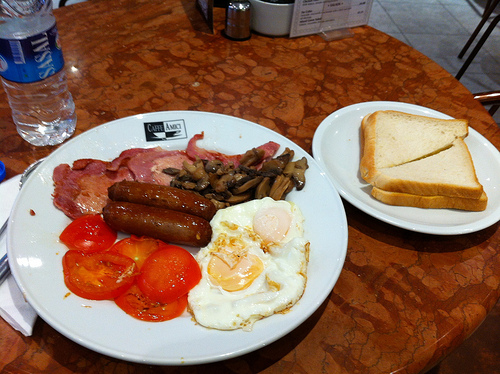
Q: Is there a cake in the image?
A: No, there are no cakes.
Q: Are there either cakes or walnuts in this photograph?
A: No, there are no cakes or walnuts.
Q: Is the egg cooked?
A: Yes, the egg is cooked.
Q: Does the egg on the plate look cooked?
A: Yes, the egg is cooked.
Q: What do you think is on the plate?
A: The egg is on the plate.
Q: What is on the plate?
A: The egg is on the plate.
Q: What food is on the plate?
A: The food is an egg.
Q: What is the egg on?
A: The egg is on the plate.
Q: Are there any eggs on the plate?
A: Yes, there is an egg on the plate.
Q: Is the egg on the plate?
A: Yes, the egg is on the plate.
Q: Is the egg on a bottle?
A: No, the egg is on the plate.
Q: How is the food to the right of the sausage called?
A: The food is an egg.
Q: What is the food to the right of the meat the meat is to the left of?
A: The food is an egg.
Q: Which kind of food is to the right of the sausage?
A: The food is an egg.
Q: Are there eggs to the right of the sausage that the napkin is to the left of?
A: Yes, there is an egg to the right of the sausage.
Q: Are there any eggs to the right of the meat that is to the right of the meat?
A: Yes, there is an egg to the right of the sausage.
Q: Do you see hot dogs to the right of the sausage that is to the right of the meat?
A: No, there is an egg to the right of the sausage.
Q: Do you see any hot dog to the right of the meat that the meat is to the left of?
A: No, there is an egg to the right of the sausage.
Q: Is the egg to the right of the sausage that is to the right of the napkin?
A: Yes, the egg is to the right of the sausage.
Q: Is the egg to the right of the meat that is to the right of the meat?
A: Yes, the egg is to the right of the sausage.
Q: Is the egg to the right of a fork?
A: No, the egg is to the right of the sausage.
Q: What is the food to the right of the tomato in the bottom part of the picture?
A: The food is an egg.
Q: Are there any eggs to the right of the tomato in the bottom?
A: Yes, there is an egg to the right of the tomato.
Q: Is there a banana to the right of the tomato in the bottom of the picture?
A: No, there is an egg to the right of the tomato.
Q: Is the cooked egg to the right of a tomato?
A: Yes, the egg is to the right of a tomato.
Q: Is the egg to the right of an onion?
A: No, the egg is to the right of a tomato.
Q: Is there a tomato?
A: Yes, there is a tomato.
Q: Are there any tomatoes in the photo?
A: Yes, there is a tomato.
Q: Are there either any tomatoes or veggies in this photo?
A: Yes, there is a tomato.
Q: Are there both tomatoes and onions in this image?
A: No, there is a tomato but no onions.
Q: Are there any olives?
A: No, there are no olives.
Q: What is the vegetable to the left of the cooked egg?
A: The vegetable is a tomato.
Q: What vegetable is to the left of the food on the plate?
A: The vegetable is a tomato.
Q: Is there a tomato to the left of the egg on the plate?
A: Yes, there is a tomato to the left of the egg.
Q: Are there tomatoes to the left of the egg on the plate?
A: Yes, there is a tomato to the left of the egg.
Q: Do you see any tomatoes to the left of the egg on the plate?
A: Yes, there is a tomato to the left of the egg.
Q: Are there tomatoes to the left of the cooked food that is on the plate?
A: Yes, there is a tomato to the left of the egg.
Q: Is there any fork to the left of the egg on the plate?
A: No, there is a tomato to the left of the egg.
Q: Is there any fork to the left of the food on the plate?
A: No, there is a tomato to the left of the egg.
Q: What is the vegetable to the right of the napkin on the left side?
A: The vegetable is a tomato.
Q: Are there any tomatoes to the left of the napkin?
A: No, the tomato is to the right of the napkin.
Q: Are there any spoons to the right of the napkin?
A: No, there is a tomato to the right of the napkin.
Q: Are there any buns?
A: No, there are no buns.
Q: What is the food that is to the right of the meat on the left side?
A: The food is a sausage.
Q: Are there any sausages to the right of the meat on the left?
A: Yes, there is a sausage to the right of the meat.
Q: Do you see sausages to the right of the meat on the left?
A: Yes, there is a sausage to the right of the meat.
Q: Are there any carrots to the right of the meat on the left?
A: No, there is a sausage to the right of the meat.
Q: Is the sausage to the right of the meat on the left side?
A: Yes, the sausage is to the right of the meat.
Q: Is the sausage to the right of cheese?
A: No, the sausage is to the right of the meat.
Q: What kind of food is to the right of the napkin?
A: The food is a sausage.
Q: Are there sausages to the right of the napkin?
A: Yes, there is a sausage to the right of the napkin.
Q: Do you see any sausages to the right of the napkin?
A: Yes, there is a sausage to the right of the napkin.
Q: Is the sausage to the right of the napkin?
A: Yes, the sausage is to the right of the napkin.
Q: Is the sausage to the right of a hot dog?
A: No, the sausage is to the right of the napkin.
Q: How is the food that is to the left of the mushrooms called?
A: The food is a sausage.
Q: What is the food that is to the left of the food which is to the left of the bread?
A: The food is a sausage.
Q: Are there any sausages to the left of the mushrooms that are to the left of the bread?
A: Yes, there is a sausage to the left of the mushrooms.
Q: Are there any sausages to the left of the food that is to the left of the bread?
A: Yes, there is a sausage to the left of the mushrooms.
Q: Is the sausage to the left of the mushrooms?
A: Yes, the sausage is to the left of the mushrooms.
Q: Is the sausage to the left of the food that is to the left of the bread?
A: Yes, the sausage is to the left of the mushrooms.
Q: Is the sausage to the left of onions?
A: No, the sausage is to the left of the mushrooms.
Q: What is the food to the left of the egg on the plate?
A: The food is a sausage.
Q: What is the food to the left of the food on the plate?
A: The food is a sausage.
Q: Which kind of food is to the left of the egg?
A: The food is a sausage.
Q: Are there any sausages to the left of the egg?
A: Yes, there is a sausage to the left of the egg.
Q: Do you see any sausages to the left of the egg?
A: Yes, there is a sausage to the left of the egg.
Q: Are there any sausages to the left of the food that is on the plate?
A: Yes, there is a sausage to the left of the egg.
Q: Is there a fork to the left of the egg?
A: No, there is a sausage to the left of the egg.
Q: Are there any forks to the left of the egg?
A: No, there is a sausage to the left of the egg.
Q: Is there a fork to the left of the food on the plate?
A: No, there is a sausage to the left of the egg.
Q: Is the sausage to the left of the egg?
A: Yes, the sausage is to the left of the egg.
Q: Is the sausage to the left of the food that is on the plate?
A: Yes, the sausage is to the left of the egg.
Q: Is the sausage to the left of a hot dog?
A: No, the sausage is to the left of the egg.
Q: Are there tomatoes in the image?
A: Yes, there is a tomato.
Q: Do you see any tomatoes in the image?
A: Yes, there is a tomato.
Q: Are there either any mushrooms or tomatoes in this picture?
A: Yes, there is a tomato.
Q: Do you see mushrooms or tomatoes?
A: Yes, there is a tomato.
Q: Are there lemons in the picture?
A: No, there are no lemons.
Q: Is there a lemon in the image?
A: No, there are no lemons.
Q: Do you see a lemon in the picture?
A: No, there are no lemons.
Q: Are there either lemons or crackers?
A: No, there are no lemons or crackers.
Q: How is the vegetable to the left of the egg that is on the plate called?
A: The vegetable is a tomato.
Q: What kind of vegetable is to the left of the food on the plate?
A: The vegetable is a tomato.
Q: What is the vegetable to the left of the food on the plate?
A: The vegetable is a tomato.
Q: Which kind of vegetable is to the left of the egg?
A: The vegetable is a tomato.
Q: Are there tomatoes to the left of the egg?
A: Yes, there is a tomato to the left of the egg.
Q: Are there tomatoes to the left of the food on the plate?
A: Yes, there is a tomato to the left of the egg.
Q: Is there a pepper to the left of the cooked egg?
A: No, there is a tomato to the left of the egg.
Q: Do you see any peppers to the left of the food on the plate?
A: No, there is a tomato to the left of the egg.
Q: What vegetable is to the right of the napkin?
A: The vegetable is a tomato.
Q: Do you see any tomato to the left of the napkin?
A: No, the tomato is to the right of the napkin.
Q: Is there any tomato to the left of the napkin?
A: No, the tomato is to the right of the napkin.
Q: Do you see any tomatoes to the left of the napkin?
A: No, the tomato is to the right of the napkin.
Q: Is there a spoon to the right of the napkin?
A: No, there is a tomato to the right of the napkin.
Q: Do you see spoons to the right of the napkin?
A: No, there is a tomato to the right of the napkin.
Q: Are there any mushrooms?
A: Yes, there are mushrooms.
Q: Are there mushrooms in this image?
A: Yes, there are mushrooms.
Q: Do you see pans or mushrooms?
A: Yes, there are mushrooms.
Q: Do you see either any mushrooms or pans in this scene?
A: Yes, there are mushrooms.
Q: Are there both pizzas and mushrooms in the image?
A: No, there are mushrooms but no pizzas.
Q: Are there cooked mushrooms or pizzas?
A: Yes, there are cooked mushrooms.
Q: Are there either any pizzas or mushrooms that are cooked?
A: Yes, the mushrooms are cooked.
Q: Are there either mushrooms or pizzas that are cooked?
A: Yes, the mushrooms are cooked.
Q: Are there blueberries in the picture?
A: No, there are no blueberries.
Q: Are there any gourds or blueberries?
A: No, there are no blueberries or gourds.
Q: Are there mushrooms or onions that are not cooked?
A: No, there are mushrooms but they are cooked.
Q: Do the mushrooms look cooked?
A: Yes, the mushrooms are cooked.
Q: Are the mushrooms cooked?
A: Yes, the mushrooms are cooked.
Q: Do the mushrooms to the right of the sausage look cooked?
A: Yes, the mushrooms are cooked.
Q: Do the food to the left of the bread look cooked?
A: Yes, the mushrooms are cooked.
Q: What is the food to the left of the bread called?
A: The food is mushrooms.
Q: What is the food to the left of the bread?
A: The food is mushrooms.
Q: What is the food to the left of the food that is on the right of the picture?
A: The food is mushrooms.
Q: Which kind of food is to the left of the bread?
A: The food is mushrooms.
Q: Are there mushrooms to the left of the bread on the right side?
A: Yes, there are mushrooms to the left of the bread.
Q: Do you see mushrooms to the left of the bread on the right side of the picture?
A: Yes, there are mushrooms to the left of the bread.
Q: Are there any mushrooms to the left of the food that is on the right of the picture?
A: Yes, there are mushrooms to the left of the bread.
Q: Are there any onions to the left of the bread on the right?
A: No, there are mushrooms to the left of the bread.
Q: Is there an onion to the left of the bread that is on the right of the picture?
A: No, there are mushrooms to the left of the bread.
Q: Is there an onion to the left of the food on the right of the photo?
A: No, there are mushrooms to the left of the bread.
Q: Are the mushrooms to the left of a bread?
A: Yes, the mushrooms are to the left of a bread.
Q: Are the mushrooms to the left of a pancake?
A: No, the mushrooms are to the left of a bread.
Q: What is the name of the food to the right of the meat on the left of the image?
A: The food is mushrooms.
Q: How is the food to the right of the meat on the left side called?
A: The food is mushrooms.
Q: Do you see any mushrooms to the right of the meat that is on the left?
A: Yes, there are mushrooms to the right of the meat.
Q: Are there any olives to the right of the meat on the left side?
A: No, there are mushrooms to the right of the meat.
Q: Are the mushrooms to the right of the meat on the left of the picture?
A: Yes, the mushrooms are to the right of the meat.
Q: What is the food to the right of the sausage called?
A: The food is mushrooms.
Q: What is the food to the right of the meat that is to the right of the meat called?
A: The food is mushrooms.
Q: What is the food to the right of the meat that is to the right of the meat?
A: The food is mushrooms.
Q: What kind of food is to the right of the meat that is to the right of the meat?
A: The food is mushrooms.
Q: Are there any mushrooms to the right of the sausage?
A: Yes, there are mushrooms to the right of the sausage.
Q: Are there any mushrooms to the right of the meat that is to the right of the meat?
A: Yes, there are mushrooms to the right of the sausage.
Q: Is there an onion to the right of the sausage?
A: No, there are mushrooms to the right of the sausage.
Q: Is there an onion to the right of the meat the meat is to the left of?
A: No, there are mushrooms to the right of the sausage.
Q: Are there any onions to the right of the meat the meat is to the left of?
A: No, there are mushrooms to the right of the sausage.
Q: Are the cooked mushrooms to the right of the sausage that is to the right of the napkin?
A: Yes, the mushrooms are to the right of the sausage.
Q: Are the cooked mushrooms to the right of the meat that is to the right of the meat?
A: Yes, the mushrooms are to the right of the sausage.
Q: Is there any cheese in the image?
A: No, there is no cheese.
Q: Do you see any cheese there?
A: No, there is no cheese.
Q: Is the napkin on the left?
A: Yes, the napkin is on the left of the image.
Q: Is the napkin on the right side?
A: No, the napkin is on the left of the image.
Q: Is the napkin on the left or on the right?
A: The napkin is on the left of the image.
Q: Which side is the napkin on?
A: The napkin is on the left of the image.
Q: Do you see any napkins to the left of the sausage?
A: Yes, there is a napkin to the left of the sausage.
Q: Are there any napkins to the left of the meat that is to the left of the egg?
A: Yes, there is a napkin to the left of the sausage.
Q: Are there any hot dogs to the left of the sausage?
A: No, there is a napkin to the left of the sausage.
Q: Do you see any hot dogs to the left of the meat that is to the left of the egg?
A: No, there is a napkin to the left of the sausage.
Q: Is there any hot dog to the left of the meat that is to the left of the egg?
A: No, there is a napkin to the left of the sausage.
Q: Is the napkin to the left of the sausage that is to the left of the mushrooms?
A: Yes, the napkin is to the left of the sausage.